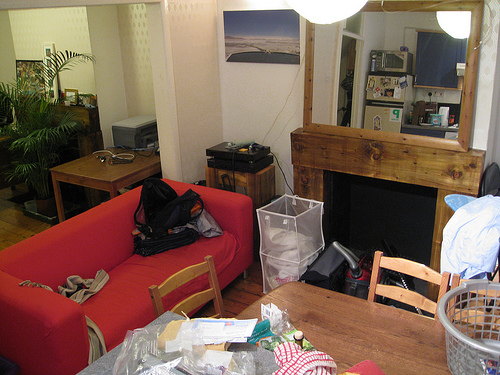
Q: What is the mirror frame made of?
A: Wood.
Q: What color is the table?
A: Brown.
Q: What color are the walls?
A: White.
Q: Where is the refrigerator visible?
A: Mirror.